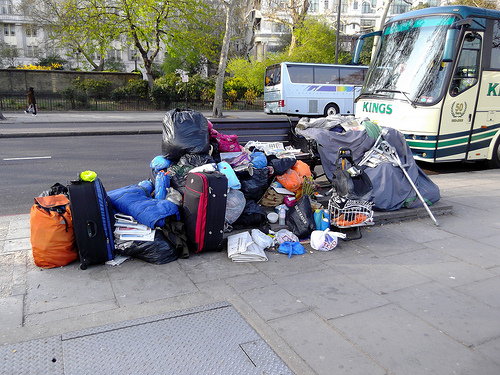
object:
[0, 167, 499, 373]
sidewalk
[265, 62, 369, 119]
bus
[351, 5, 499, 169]
bus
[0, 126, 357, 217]
road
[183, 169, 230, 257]
suitcase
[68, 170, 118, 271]
suitcase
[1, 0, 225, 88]
tree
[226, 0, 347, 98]
tree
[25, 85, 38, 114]
person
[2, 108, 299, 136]
sidewalk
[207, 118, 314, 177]
bench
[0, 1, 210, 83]
building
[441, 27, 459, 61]
side view mirror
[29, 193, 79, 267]
bag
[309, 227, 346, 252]
bag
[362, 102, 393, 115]
writing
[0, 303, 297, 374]
grate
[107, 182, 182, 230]
coat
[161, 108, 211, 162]
trash bag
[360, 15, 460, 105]
windshield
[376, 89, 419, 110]
wiper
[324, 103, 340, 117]
wheel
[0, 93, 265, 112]
fence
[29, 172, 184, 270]
stuff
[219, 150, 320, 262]
stuff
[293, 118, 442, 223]
stuff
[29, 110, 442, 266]
pile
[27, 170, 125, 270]
stuf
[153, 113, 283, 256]
stuf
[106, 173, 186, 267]
stuf